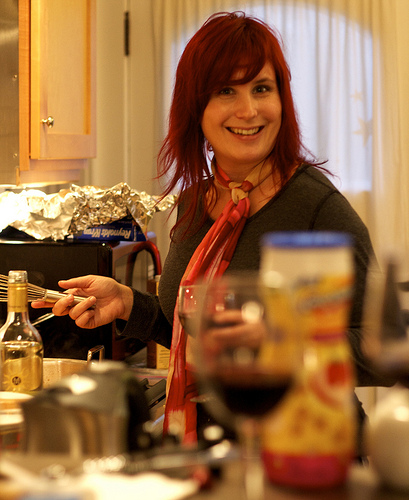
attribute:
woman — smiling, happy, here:
[142, 21, 389, 426]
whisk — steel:
[10, 260, 116, 327]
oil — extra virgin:
[0, 210, 61, 417]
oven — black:
[3, 194, 142, 379]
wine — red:
[178, 286, 318, 417]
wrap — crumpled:
[14, 170, 177, 240]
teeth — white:
[224, 116, 301, 163]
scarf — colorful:
[200, 154, 287, 202]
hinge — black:
[101, 12, 142, 70]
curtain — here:
[267, 9, 405, 221]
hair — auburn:
[123, 20, 349, 170]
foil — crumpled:
[1, 181, 173, 232]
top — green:
[173, 199, 403, 412]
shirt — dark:
[125, 176, 392, 443]